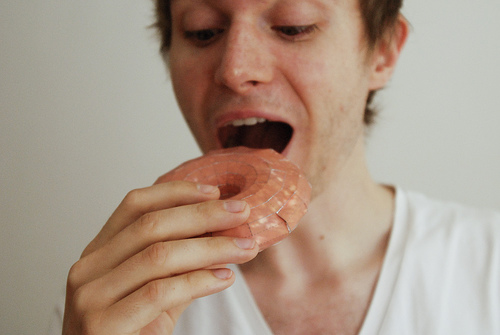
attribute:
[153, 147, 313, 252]
donut — glazed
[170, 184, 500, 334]
shirt — white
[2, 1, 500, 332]
wall — white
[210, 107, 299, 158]
mouth — open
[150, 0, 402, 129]
hair — brown